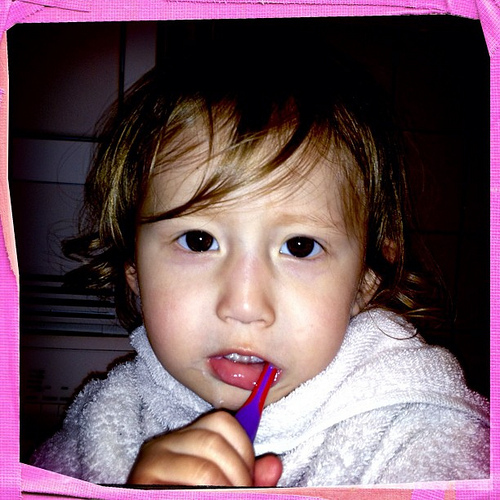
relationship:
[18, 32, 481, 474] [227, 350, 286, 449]
toddler with toothbrush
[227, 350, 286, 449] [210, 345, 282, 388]
toothbrush in mouth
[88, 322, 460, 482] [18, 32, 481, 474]
shirt on child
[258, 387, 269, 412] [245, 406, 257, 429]
red and purple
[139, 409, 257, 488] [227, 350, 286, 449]
hand holding toothbrush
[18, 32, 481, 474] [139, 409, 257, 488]
child has hand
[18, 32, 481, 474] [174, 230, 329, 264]
child has eyes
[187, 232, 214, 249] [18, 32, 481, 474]
brown eyed child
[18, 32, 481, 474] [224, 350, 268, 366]
child has teeth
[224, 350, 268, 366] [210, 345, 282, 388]
teeth in mouth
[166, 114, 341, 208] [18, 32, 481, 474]
forehead of child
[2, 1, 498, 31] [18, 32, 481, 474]
border around photo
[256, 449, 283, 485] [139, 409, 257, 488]
thumb on hand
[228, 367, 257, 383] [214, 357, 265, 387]
wet lower lip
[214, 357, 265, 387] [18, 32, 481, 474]
lip on child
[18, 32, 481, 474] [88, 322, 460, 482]
baby wearing towel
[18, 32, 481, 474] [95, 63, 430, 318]
baby has hair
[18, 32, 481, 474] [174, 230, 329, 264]
baby has eyes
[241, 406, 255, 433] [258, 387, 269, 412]
blue and red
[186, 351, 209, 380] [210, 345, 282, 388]
toothpaste around mouth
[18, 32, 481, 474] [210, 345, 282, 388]
baby has mouth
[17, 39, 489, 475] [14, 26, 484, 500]
indoor bathroom scene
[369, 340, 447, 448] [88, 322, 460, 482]
fluffy cloth robe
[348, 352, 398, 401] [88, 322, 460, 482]
white fluffy robe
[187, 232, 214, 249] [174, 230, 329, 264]
black almond eyes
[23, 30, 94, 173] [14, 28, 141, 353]
white background walls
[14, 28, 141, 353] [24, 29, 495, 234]
walls in background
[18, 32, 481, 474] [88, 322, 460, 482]
baby wearing cloth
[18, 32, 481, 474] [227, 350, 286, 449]
baby holding toothbrush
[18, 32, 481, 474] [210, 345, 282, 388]
baby has lips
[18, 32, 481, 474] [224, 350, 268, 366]
child brushing teeth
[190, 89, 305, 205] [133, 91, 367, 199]
long swept bangs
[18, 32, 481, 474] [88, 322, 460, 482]
child wearing robe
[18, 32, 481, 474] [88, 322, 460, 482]
child in robe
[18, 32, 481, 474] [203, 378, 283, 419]
child has chin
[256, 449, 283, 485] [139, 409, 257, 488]
thumb underneath fingers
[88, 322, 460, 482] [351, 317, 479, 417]
robe has hood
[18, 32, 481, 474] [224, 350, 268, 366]
kid brushing teeth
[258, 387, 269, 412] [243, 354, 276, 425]
red toothbrush handle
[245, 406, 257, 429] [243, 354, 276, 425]
purple toothbrush handle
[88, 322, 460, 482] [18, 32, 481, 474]
towel wrapped child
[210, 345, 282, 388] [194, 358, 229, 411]
mouth with drool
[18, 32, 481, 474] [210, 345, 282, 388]
child has mouth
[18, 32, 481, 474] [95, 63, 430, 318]
kid with hair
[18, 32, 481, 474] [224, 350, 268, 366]
child's white teeth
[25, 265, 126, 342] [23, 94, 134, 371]
vent for building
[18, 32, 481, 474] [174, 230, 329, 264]
kid has eyes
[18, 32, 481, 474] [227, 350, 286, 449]
kid holding toothbrush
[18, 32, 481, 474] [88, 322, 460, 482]
kid wearing towel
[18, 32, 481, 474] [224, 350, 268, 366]
kid has teeth